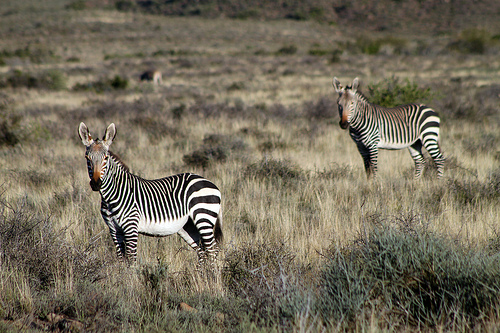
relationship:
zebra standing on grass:
[78, 121, 227, 271] [105, 263, 113, 291]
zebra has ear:
[78, 121, 227, 271] [78, 122, 94, 148]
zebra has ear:
[332, 76, 446, 181] [104, 123, 117, 147]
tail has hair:
[217, 205, 225, 248] [215, 226, 223, 243]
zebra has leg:
[332, 76, 446, 181] [421, 133, 446, 181]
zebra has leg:
[78, 121, 227, 271] [191, 214, 222, 277]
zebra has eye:
[78, 121, 227, 271] [105, 156, 109, 160]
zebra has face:
[78, 121, 227, 271] [85, 151, 109, 192]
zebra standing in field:
[332, 76, 446, 181] [1, 2, 500, 330]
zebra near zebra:
[78, 121, 227, 271] [332, 76, 446, 181]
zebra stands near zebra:
[78, 121, 227, 271] [332, 76, 446, 181]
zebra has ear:
[332, 76, 446, 181] [351, 77, 361, 92]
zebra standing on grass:
[332, 76, 446, 181] [347, 164, 355, 181]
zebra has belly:
[78, 121, 227, 271] [139, 216, 189, 237]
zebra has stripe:
[78, 121, 227, 271] [188, 195, 221, 211]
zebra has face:
[332, 76, 446, 181] [337, 98, 355, 129]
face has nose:
[85, 151, 109, 192] [90, 180, 104, 192]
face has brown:
[337, 98, 355, 129] [340, 114, 348, 121]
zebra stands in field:
[78, 121, 227, 271] [1, 2, 500, 330]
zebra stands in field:
[332, 76, 446, 181] [1, 2, 500, 330]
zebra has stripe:
[78, 121, 227, 271] [138, 177, 149, 224]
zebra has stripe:
[332, 76, 446, 181] [378, 107, 386, 143]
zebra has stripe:
[78, 121, 227, 271] [117, 171, 133, 223]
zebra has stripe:
[78, 121, 227, 271] [185, 179, 219, 215]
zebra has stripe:
[332, 76, 446, 181] [418, 110, 440, 131]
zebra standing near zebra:
[78, 121, 227, 271] [332, 76, 446, 181]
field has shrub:
[1, 2, 500, 330] [284, 9, 312, 20]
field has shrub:
[1, 2, 500, 330] [440, 25, 490, 55]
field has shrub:
[1, 2, 500, 330] [64, 0, 86, 10]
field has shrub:
[1, 2, 500, 330] [139, 0, 163, 16]